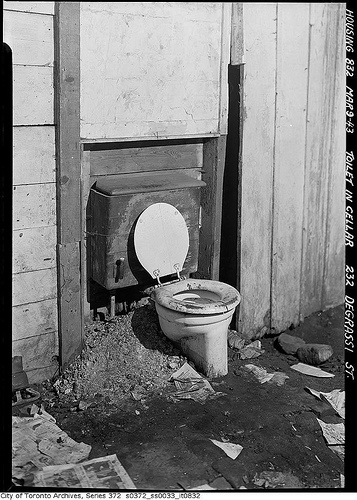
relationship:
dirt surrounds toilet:
[46, 304, 215, 400] [91, 164, 241, 379]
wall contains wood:
[248, 8, 342, 312] [240, 4, 342, 174]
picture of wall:
[6, 10, 342, 483] [248, 8, 342, 312]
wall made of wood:
[248, 8, 342, 312] [240, 4, 342, 174]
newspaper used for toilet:
[15, 413, 141, 488] [91, 164, 241, 379]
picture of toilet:
[6, 10, 342, 483] [91, 164, 241, 379]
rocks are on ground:
[51, 357, 199, 422] [16, 390, 346, 485]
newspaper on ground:
[15, 413, 141, 488] [16, 390, 346, 485]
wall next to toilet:
[248, 8, 342, 312] [91, 164, 241, 379]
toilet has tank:
[91, 164, 241, 379] [91, 177, 199, 288]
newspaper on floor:
[15, 413, 141, 488] [16, 390, 346, 485]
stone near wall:
[276, 326, 334, 368] [248, 8, 342, 312]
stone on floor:
[276, 326, 334, 368] [16, 390, 346, 485]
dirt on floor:
[46, 304, 215, 400] [16, 390, 346, 485]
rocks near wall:
[51, 357, 199, 422] [248, 8, 342, 312]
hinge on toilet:
[150, 264, 184, 284] [91, 164, 241, 379]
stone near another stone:
[276, 326, 334, 368] [277, 330, 302, 355]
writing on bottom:
[5, 491, 208, 498] [10, 479, 353, 497]